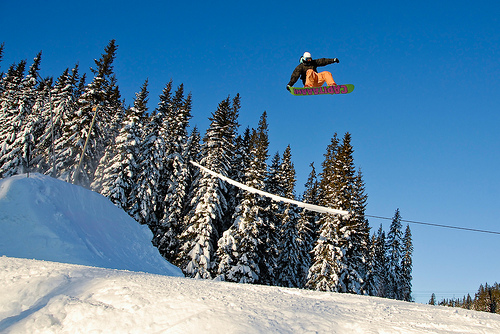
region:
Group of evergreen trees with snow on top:
[5, 27, 419, 292]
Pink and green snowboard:
[284, 86, 366, 103]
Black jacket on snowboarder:
[285, 47, 332, 82]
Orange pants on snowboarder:
[303, 66, 346, 83]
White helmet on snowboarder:
[296, 45, 321, 65]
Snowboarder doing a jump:
[267, 33, 364, 105]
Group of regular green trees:
[414, 283, 499, 317]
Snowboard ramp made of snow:
[4, 172, 172, 276]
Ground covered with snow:
[2, 250, 494, 332]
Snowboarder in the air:
[246, 38, 361, 103]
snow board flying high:
[276, 39, 372, 109]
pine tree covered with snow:
[56, 108, 331, 280]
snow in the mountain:
[20, 174, 157, 310]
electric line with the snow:
[196, 155, 465, 242]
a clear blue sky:
[403, 42, 476, 220]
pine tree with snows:
[33, 38, 218, 277]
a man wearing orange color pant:
[306, 74, 335, 86]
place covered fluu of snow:
[17, 166, 352, 316]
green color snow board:
[288, 83, 358, 94]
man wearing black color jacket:
[288, 58, 340, 73]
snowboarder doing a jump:
[278, 39, 374, 116]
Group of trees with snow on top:
[4, 106, 303, 293]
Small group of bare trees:
[423, 286, 499, 308]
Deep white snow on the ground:
[14, 182, 487, 332]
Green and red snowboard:
[289, 78, 353, 100]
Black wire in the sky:
[364, 206, 496, 242]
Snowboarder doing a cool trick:
[269, 38, 359, 106]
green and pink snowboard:
[285, 85, 356, 95]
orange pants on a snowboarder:
[300, 68, 335, 88]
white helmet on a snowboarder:
[301, 50, 312, 62]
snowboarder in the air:
[285, 49, 357, 96]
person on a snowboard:
[284, 50, 356, 96]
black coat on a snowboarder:
[288, 55, 340, 85]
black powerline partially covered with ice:
[188, 155, 498, 267]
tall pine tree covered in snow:
[182, 90, 235, 277]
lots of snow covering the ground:
[0, 252, 497, 332]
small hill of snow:
[1, 170, 185, 282]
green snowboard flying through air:
[287, 82, 357, 99]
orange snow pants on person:
[302, 69, 337, 86]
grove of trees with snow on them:
[0, 35, 421, 299]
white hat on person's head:
[301, 51, 313, 61]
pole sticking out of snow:
[71, 102, 101, 183]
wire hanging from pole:
[96, 102, 498, 237]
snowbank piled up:
[1, 171, 178, 273]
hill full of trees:
[426, 282, 498, 312]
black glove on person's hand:
[334, 57, 339, 64]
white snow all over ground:
[4, 174, 499, 332]